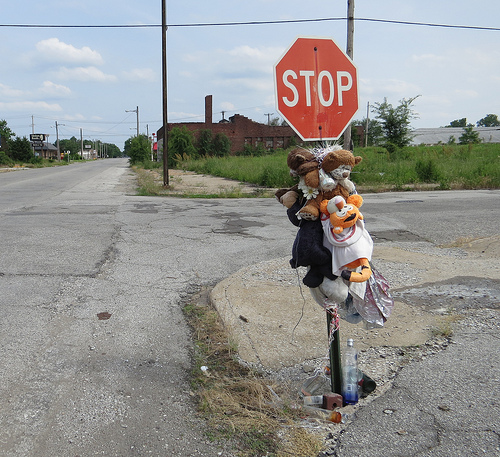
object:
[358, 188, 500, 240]
floor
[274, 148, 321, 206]
stuffed animals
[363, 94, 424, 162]
tree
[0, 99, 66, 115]
clouds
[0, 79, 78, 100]
clouds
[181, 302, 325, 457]
grass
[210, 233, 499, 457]
sidewalk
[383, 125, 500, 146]
building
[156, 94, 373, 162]
building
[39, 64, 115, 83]
cloud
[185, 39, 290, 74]
cloud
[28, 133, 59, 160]
business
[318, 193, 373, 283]
tiger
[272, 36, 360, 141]
sign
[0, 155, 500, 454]
street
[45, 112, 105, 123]
clouds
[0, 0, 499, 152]
blue sky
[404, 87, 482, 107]
white cloud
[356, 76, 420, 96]
white cloud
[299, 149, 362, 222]
stuffed animals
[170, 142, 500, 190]
grass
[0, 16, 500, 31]
powerline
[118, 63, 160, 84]
clouds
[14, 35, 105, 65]
cloud